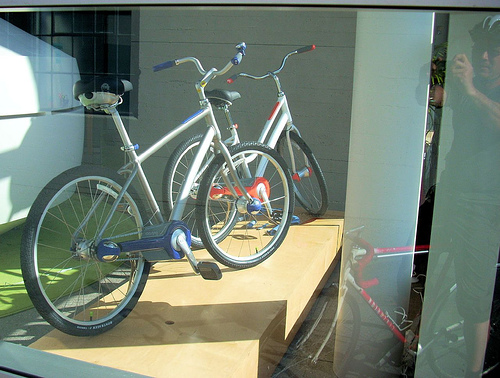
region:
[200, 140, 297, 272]
black rubber bike tire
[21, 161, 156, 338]
black rubber bike tire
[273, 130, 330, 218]
black rubber bike tire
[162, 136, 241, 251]
black rubber bike tire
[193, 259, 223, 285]
black plastic bike peddle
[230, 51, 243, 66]
blue colored bike grip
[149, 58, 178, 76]
blue colored bike grip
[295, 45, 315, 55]
red colored bike grip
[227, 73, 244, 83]
red colored bike grip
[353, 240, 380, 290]
red colored bike grip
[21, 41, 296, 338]
A gray and blue bike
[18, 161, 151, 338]
A wheel on a bike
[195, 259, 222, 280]
A pedal on a bike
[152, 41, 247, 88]
Handle bars on a bike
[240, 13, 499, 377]
Reflection of man on a red bike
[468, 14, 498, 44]
Reflection of a helmet on a man's head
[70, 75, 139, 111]
Seat of a bike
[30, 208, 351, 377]
A wooden platfom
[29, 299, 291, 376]
A shadow being casted on wooden platform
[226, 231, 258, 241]
Shadow of bikes pedal.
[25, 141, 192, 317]
the back wheel on a bike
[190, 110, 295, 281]
the front wheel on a bike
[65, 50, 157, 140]
a seat on a bike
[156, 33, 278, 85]
the handlebars on a bike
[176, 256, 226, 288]
a paddle on a bike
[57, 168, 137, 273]
spokes on a bike wheel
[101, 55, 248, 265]
the frame on a bike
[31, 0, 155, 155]
a window on a house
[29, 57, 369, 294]
two bikes near eachother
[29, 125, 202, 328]
a bike on the ground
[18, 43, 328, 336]
two bikes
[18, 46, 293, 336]
a blue bicycle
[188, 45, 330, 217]
a red bicycle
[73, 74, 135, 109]
the seat of the bicycle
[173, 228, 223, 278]
the pedal of the bike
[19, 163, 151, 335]
the tire of the bicycle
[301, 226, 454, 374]
a reflection of a red bicycle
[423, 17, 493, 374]
a man on a bike taking a picture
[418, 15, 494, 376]
a man wearing a helmet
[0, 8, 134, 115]
a reflection of a window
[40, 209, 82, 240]
Silver spoke on the bicycle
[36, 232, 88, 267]
Silver spoke on the bicycle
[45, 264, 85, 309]
Silver spoke on the bicycle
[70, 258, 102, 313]
Silver spoke on the bicycle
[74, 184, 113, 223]
Silver spoke on the bicycle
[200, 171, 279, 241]
Silver spoke on the bicycle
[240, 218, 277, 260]
Silver spoke on the bicycle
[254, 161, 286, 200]
Silver spoke on the bicycle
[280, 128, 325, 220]
Silver spoke on the bicycle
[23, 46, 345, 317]
Bicycles on display